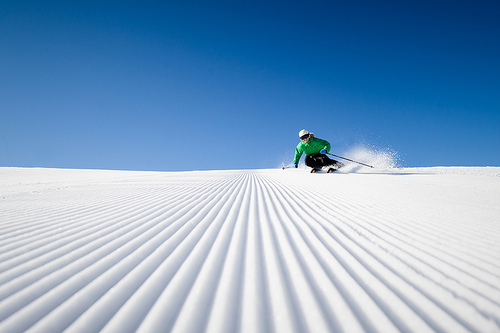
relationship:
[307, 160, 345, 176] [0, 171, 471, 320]
skis in snow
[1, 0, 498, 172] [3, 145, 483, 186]
sky above horizon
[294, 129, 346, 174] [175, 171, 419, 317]
man going down slope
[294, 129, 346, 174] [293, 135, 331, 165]
man wearing green coat